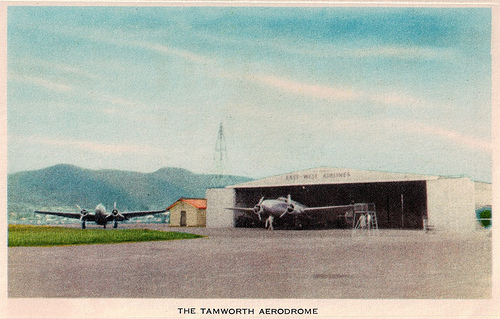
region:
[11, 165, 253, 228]
The hills in the distance.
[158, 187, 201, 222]
The tan building on the left.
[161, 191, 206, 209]
The red roof of the tan building.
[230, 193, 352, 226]
The plane in the hangar.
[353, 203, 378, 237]
The metal laddar next to the people.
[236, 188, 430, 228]
The opening of the hangar.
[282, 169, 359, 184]
The letters on the roof of the hangar.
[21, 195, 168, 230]
The plane on the left.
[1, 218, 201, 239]
The grass in front of the plane.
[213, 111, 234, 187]
The metal tower in the distance.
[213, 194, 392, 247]
the plane is silver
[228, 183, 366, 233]
the plane is silver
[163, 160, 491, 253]
a white garage for plane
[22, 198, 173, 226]
a plane on a run way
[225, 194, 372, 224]
a plane in a building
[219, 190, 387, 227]
a plane in a hanger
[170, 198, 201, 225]
a yellow building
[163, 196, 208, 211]
a red roof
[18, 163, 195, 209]
tree covered hills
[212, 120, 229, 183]
a metal tower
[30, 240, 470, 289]
a concrete run way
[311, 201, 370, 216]
left wing on a plane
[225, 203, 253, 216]
right wing on a plane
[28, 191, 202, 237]
A plane in the runway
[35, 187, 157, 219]
A plane in the runway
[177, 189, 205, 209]
the roof is orange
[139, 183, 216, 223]
the roof is orange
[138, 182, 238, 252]
the roof is orange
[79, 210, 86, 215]
A plane engine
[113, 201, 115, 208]
A plane's propeller blade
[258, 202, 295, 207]
A plane in the hangar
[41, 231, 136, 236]
Grass in front of the plane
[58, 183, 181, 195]
A mountain range in the background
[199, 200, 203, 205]
A red roof on a building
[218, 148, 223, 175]
A metallic tower in the background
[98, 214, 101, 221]
The underside of a plane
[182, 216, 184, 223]
The door to a building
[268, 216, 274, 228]
A person under a plane